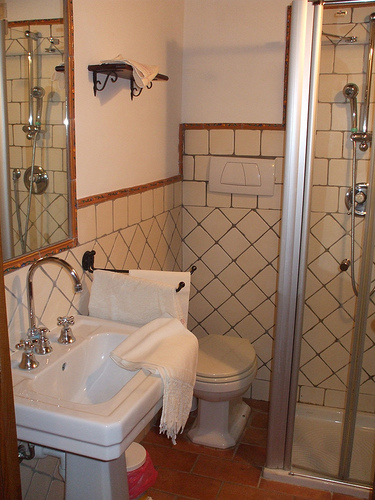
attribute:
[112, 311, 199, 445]
towel — white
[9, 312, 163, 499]
sink — white, pedestal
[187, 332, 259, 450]
toilet — white, porcelain, closed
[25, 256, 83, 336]
faucet — metal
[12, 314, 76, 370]
knobs — metal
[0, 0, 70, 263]
mirror — reflective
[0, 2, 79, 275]
frame — wood, brown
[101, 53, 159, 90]
towel — folded, white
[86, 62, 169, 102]
shelf — small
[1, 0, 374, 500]
walls — tiled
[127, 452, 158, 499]
bag — red, pink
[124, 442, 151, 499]
trashcan — small, white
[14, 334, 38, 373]
knob — hot water, silver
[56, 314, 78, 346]
knob — cold water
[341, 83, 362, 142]
shower head — handheld, silver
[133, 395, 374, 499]
floor — tiled, rust colored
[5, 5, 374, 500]
tiles — white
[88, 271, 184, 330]
towel — white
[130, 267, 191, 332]
towel — white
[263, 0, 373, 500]
shower — standing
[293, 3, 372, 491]
doors — glass